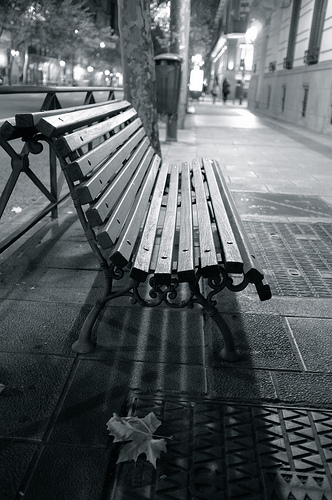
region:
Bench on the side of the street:
[16, 95, 284, 362]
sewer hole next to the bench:
[96, 387, 331, 498]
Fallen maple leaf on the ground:
[100, 410, 177, 470]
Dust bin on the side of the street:
[152, 52, 185, 144]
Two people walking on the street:
[205, 72, 231, 105]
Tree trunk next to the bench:
[113, 0, 162, 159]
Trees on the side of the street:
[3, 1, 121, 85]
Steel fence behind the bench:
[0, 84, 124, 258]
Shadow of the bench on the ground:
[25, 250, 284, 497]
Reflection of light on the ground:
[228, 109, 259, 129]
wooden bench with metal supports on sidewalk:
[0, 96, 276, 364]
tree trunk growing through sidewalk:
[112, 0, 171, 203]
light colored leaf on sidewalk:
[98, 408, 174, 467]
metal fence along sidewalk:
[0, 81, 173, 283]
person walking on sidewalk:
[220, 76, 233, 106]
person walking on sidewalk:
[208, 73, 221, 105]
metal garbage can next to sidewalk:
[149, 49, 184, 118]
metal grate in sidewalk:
[229, 216, 330, 305]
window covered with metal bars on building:
[301, 0, 328, 66]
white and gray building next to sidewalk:
[245, 0, 330, 141]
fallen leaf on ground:
[107, 410, 170, 463]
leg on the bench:
[199, 311, 295, 368]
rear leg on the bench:
[70, 303, 101, 358]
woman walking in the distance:
[220, 74, 231, 106]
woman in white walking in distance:
[213, 75, 221, 100]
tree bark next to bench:
[120, 2, 149, 104]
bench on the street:
[48, 96, 270, 368]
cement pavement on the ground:
[1, 334, 78, 490]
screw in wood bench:
[177, 243, 192, 256]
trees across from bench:
[10, 9, 97, 48]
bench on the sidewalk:
[34, 97, 293, 278]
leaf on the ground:
[104, 413, 183, 468]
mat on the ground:
[115, 384, 330, 492]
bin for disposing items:
[154, 49, 182, 115]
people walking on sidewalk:
[210, 68, 231, 104]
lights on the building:
[244, 21, 264, 44]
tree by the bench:
[104, 8, 177, 156]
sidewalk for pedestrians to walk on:
[206, 111, 282, 184]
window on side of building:
[284, 3, 299, 64]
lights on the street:
[8, 43, 123, 78]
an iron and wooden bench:
[17, 83, 294, 367]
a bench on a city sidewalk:
[18, 66, 279, 353]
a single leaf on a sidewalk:
[90, 398, 196, 494]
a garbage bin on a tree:
[151, 49, 197, 127]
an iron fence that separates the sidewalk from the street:
[1, 82, 147, 223]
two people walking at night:
[205, 63, 239, 108]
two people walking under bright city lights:
[208, 59, 244, 109]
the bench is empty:
[18, 86, 289, 369]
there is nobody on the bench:
[11, 88, 288, 370]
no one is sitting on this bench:
[12, 78, 290, 381]